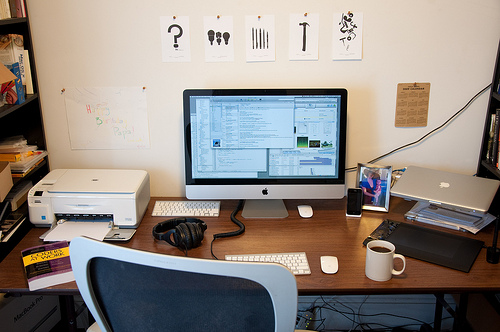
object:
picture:
[354, 165, 391, 213]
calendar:
[395, 83, 431, 128]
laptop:
[390, 164, 500, 213]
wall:
[33, 2, 498, 86]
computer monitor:
[182, 88, 350, 200]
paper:
[330, 5, 363, 62]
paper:
[391, 80, 431, 128]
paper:
[290, 11, 320, 61]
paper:
[241, 10, 275, 62]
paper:
[202, 6, 231, 62]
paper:
[160, 13, 189, 60]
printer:
[26, 167, 150, 244]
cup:
[362, 239, 406, 282]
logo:
[261, 187, 269, 195]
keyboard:
[151, 200, 221, 217]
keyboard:
[223, 251, 311, 275]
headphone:
[152, 217, 208, 250]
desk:
[0, 196, 500, 332]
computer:
[182, 88, 348, 219]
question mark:
[168, 24, 183, 48]